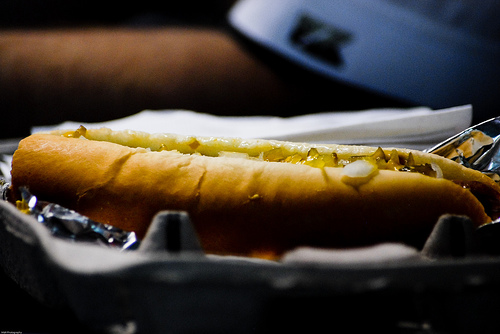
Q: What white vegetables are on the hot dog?
A: Onions.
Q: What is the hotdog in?
A: A bun.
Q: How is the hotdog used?
A: The hotdog is eaten.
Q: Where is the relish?
A: On the Hotdog.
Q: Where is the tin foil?
A: Under the hotdog.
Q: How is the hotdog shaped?
A: Long and thin.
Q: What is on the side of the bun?
A: A shadow is on the side of the bun.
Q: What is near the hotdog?
A: A white paper product.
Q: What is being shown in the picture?
A: A hotdog is being shown.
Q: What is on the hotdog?
A: There is relish on the hotdog.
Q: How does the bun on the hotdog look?
A: The hotdog bun looks fresh.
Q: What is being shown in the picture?
A: The arm of a man is being shown.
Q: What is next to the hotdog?
A: A white napkin is next to the hotdog.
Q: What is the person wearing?
A: A white shirt.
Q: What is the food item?
A: Hot dog.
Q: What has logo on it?
A: Sleeve.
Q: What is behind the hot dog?
A: Arm of a person.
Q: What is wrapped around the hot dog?
A: Foil wrapper.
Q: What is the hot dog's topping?
A: Pickle relish.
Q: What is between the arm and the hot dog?
A: Napkins.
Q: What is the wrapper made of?
A: Aluminum.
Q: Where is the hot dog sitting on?
A: Plate.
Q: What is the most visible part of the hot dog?
A: Bun.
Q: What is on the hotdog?
A: Relish and mustard.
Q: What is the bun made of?
A: White bread.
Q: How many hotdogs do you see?
A: 1 hot dog.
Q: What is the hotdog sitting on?
A: A piece of foil.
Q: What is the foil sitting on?
A: A paper plate.